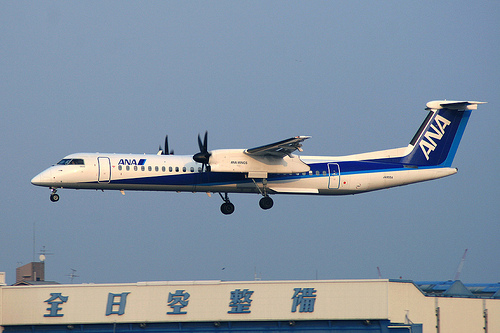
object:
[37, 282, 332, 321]
letters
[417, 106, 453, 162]
logo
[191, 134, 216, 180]
propeller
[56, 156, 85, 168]
window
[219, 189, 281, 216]
landing gear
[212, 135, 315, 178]
wing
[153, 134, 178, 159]
propellers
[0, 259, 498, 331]
building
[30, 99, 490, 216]
plane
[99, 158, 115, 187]
door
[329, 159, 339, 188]
door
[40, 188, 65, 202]
tire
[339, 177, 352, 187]
spot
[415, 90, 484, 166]
tail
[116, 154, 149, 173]
logo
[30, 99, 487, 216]
airplane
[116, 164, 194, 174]
windows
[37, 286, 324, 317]
language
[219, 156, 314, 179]
walls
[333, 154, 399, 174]
walls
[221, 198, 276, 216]
wheels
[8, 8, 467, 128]
sky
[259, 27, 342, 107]
clouds